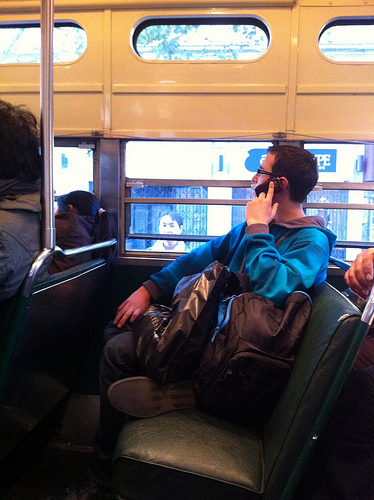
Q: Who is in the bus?
A: A man.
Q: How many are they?
A: 1.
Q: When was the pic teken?
A: During the day.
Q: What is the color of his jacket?
A: Blue.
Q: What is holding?
A: A phone.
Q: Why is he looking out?
A: Looking at people.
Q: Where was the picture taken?
A: In the bus.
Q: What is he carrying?
A: A bag.